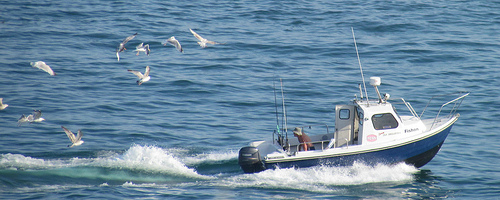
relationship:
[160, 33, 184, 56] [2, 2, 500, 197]
bird above water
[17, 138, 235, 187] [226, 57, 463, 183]
wake created by boat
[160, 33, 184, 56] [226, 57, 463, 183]
bird behind boat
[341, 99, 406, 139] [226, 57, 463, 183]
cabin on boat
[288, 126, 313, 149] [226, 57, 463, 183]
man on boat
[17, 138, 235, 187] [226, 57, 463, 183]
wake made by boat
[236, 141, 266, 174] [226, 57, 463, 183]
engine on back of boat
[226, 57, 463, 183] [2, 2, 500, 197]
boat on water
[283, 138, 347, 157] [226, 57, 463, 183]
railing on boat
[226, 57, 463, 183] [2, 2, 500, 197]
boat moving in water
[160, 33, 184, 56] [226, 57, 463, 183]
bird following boat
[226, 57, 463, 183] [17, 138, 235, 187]
boat creating wake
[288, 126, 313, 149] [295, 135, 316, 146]
man wearing shirt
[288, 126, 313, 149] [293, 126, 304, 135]
man wearing hat